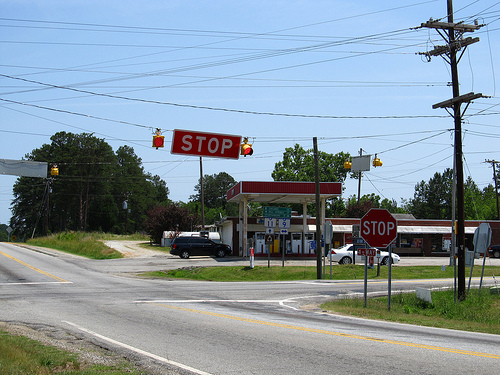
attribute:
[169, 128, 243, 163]
sign — hanging, red, white, rectangular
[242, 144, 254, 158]
light — on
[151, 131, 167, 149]
light — hanging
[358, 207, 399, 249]
sign — octagonal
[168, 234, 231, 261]
suv — black, parked, nearby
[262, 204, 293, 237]
signs — posted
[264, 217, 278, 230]
sign — white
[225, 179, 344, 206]
awning — red, white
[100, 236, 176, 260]
road — side road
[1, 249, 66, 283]
line — yellow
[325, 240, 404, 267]
car — white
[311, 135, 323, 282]
pole — wood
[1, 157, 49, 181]
sign — backwards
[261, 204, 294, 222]
sign — green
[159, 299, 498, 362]
line — yellow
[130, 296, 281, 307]
line — white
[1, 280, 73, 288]
line — white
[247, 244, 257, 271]
pole — white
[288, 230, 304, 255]
pump — white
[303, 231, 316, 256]
pump — white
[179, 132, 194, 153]
letter — white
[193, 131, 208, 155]
letter — white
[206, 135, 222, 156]
letter — white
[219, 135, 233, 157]
letter — white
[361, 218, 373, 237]
letter — white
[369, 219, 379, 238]
letter — white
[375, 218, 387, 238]
letter — white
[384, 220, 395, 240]
letter — white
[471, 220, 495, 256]
sign — backwards